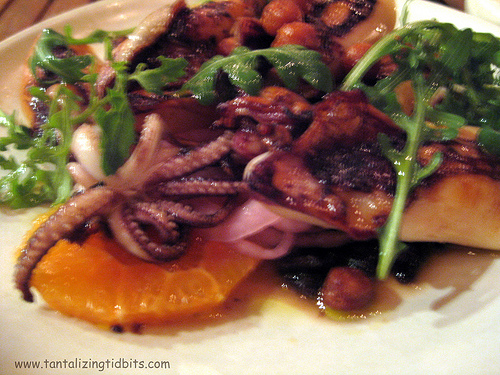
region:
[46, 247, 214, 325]
A glistening orange slice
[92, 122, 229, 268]
A portion of calamari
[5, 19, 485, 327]
A salad with fruit, greens and seafood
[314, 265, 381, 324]
A berry lying in juice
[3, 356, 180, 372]
A website address called "www.tantalizingtidbits.com"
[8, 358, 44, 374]
Three letter Ws on a tan background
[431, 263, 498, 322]
A section of plate, colored white with a shadow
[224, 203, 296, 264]
A moist, purplish onion slice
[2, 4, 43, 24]
A portion of a dark brown table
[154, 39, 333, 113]
Some salad greens in a plate of food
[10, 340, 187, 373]
this is a sentence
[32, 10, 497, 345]
this is a plate of food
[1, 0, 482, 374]
this is a white plate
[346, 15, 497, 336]
this is a green vegetable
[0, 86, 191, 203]
this is a green vegetable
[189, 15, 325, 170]
this is a green vegetable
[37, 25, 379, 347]
this is a food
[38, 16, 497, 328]
this is a mixture of vegetable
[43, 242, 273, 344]
this is an orange vegetable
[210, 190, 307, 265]
this is an onion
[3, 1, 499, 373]
a plate filled with food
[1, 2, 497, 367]
a pile of food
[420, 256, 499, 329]
shadow on the plate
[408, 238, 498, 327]
shadow from the food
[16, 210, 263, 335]
orange slice of food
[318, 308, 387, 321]
sauce on the plate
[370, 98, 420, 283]
thin green stem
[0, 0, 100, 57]
edge of a plate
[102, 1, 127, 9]
light shining on the plate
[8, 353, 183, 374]
website address